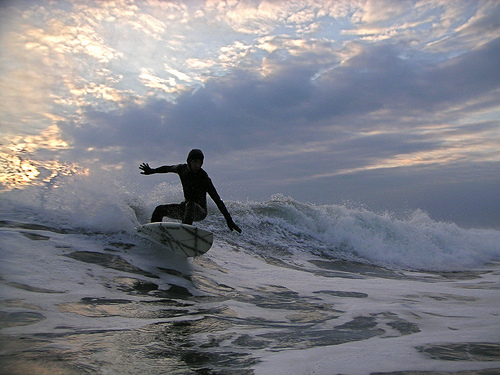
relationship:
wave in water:
[0, 156, 498, 270] [1, 162, 499, 373]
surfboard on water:
[136, 222, 214, 258] [1, 162, 499, 373]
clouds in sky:
[1, 0, 500, 233] [0, 1, 500, 234]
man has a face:
[140, 148, 243, 232] [190, 156, 204, 172]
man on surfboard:
[140, 148, 243, 232] [136, 222, 214, 258]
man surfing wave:
[140, 148, 243, 232] [0, 156, 498, 270]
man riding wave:
[140, 148, 243, 232] [0, 156, 498, 270]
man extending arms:
[140, 148, 243, 232] [138, 161, 242, 233]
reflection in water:
[123, 228, 245, 374] [1, 162, 499, 373]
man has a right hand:
[140, 148, 243, 232] [138, 161, 153, 176]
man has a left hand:
[140, 148, 243, 232] [226, 220, 243, 235]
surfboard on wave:
[136, 222, 214, 258] [0, 156, 498, 270]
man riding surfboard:
[140, 148, 243, 232] [136, 222, 214, 258]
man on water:
[140, 148, 243, 232] [1, 162, 499, 373]